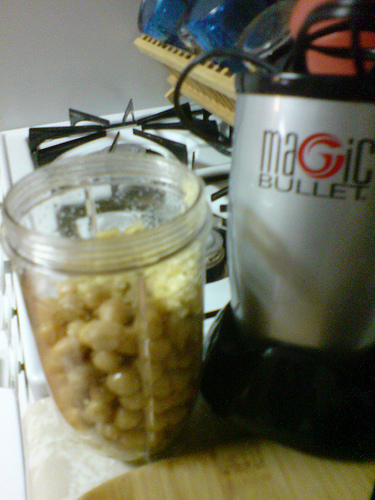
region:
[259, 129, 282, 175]
black letter on appliance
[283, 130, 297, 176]
black letter on appliance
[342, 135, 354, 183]
black letter on appliance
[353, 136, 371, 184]
black letter on appliance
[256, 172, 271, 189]
black letter on appliance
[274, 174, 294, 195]
black letter on appliance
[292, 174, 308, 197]
black letter on appliance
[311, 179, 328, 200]
black letter on appliance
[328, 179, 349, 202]
black letter on appliance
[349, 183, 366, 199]
black letter on appliance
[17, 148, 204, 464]
corn in a cup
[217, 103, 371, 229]
magic bullet on the table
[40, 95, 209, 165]
white and black stove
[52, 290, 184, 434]
corn kernels in a glass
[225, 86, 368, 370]
black and silver magic bullet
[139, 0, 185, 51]
blue cup on the shelf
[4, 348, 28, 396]
knob on the stove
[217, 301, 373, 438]
black base on the blender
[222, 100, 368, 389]
this is a blender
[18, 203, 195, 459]
a container with nuts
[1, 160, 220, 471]
the container is made of glass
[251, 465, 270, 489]
this is the table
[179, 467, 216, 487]
this is the table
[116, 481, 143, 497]
this is the table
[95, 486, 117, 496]
this is the table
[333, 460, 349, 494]
this is the table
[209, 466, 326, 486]
this is the table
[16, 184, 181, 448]
clear cup with legumes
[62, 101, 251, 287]
black covers on stove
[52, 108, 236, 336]
stove is white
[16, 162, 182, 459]
plastic cup on wood board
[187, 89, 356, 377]
black and silver juicer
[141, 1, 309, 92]
blue cups behind juicer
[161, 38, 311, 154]
black cord on juicer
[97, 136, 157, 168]
grey burners on oven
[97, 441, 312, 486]
board is light brown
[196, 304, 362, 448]
black base for juicer